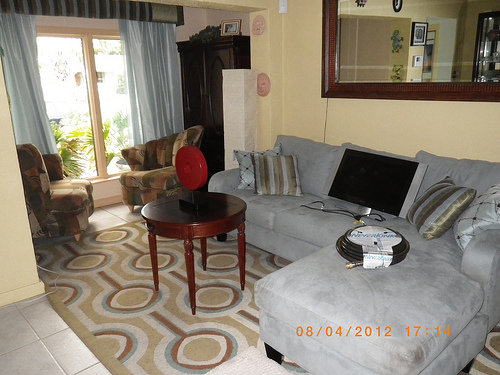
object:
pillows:
[249, 152, 305, 197]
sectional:
[207, 134, 499, 374]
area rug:
[31, 216, 293, 374]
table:
[142, 191, 247, 316]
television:
[326, 145, 428, 222]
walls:
[214, 0, 498, 164]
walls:
[1, 54, 45, 308]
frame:
[33, 25, 138, 184]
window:
[93, 36, 134, 182]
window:
[35, 36, 98, 180]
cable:
[335, 223, 410, 270]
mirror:
[336, 0, 500, 83]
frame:
[320, 0, 500, 103]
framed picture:
[221, 19, 243, 37]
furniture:
[17, 36, 499, 374]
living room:
[1, 0, 500, 374]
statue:
[175, 146, 212, 215]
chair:
[118, 124, 204, 213]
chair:
[16, 143, 93, 241]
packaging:
[348, 223, 401, 268]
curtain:
[118, 18, 184, 149]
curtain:
[1, 13, 58, 154]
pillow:
[233, 142, 281, 190]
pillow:
[405, 176, 478, 241]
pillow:
[452, 183, 500, 251]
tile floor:
[1, 200, 144, 374]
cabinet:
[174, 35, 251, 191]